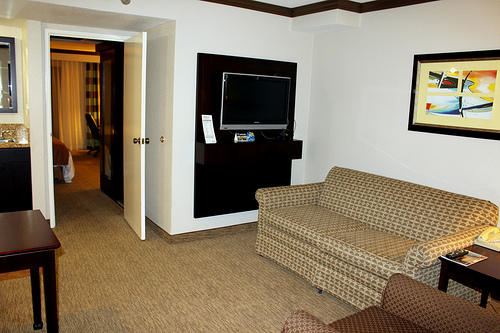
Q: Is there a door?
A: Yes, there is a door.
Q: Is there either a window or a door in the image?
A: Yes, there is a door.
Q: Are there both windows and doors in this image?
A: Yes, there are both a door and a window.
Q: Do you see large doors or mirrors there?
A: Yes, there is a large door.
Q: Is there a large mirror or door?
A: Yes, there is a large door.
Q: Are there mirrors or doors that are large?
A: Yes, the door is large.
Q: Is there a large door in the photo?
A: Yes, there is a large door.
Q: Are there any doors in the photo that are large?
A: Yes, there is a door that is large.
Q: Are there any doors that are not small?
A: Yes, there is a large door.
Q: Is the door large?
A: Yes, the door is large.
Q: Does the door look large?
A: Yes, the door is large.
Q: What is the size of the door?
A: The door is large.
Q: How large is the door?
A: The door is large.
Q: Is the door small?
A: No, the door is large.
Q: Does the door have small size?
A: No, the door is large.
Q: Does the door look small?
A: No, the door is large.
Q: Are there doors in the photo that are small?
A: No, there is a door but it is large.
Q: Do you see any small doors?
A: No, there is a door but it is large.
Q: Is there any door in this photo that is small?
A: No, there is a door but it is large.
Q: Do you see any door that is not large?
A: No, there is a door but it is large.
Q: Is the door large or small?
A: The door is large.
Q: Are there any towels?
A: No, there are no towels.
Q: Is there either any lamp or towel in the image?
A: No, there are no towels or lamps.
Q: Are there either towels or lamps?
A: No, there are no towels or lamps.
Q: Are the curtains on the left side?
A: Yes, the curtains are on the left of the image.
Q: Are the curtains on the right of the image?
A: No, the curtains are on the left of the image.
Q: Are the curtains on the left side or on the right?
A: The curtains are on the left of the image.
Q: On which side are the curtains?
A: The curtains are on the left of the image.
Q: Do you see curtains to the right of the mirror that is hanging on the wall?
A: Yes, there are curtains to the right of the mirror.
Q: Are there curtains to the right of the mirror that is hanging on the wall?
A: Yes, there are curtains to the right of the mirror.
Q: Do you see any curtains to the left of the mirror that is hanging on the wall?
A: No, the curtains are to the right of the mirror.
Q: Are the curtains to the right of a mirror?
A: Yes, the curtains are to the right of a mirror.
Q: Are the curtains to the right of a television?
A: No, the curtains are to the right of a mirror.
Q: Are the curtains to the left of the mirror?
A: No, the curtains are to the right of the mirror.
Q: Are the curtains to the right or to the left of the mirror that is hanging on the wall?
A: The curtains are to the right of the mirror.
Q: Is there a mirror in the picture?
A: Yes, there is a mirror.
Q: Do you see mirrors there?
A: Yes, there is a mirror.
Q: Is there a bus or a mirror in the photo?
A: Yes, there is a mirror.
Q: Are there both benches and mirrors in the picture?
A: No, there is a mirror but no benches.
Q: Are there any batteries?
A: No, there are no batteries.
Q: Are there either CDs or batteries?
A: No, there are no batteries or cds.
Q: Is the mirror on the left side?
A: Yes, the mirror is on the left of the image.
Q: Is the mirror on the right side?
A: No, the mirror is on the left of the image.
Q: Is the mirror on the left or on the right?
A: The mirror is on the left of the image.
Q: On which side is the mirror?
A: The mirror is on the left of the image.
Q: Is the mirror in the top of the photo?
A: Yes, the mirror is in the top of the image.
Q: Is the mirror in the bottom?
A: No, the mirror is in the top of the image.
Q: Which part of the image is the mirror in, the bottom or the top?
A: The mirror is in the top of the image.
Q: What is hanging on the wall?
A: The mirror is hanging on the wall.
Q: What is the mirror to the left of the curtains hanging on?
A: The mirror is hanging on the wall.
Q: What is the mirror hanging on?
A: The mirror is hanging on the wall.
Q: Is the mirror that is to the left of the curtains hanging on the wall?
A: Yes, the mirror is hanging on the wall.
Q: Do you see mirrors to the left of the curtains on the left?
A: Yes, there is a mirror to the left of the curtains.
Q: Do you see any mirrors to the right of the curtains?
A: No, the mirror is to the left of the curtains.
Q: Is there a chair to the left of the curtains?
A: No, there is a mirror to the left of the curtains.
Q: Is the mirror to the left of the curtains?
A: Yes, the mirror is to the left of the curtains.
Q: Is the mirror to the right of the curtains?
A: No, the mirror is to the left of the curtains.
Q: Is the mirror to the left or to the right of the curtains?
A: The mirror is to the left of the curtains.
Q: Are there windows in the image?
A: Yes, there is a window.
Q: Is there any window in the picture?
A: Yes, there is a window.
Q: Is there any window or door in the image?
A: Yes, there is a window.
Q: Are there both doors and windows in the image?
A: Yes, there are both a window and a door.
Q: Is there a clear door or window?
A: Yes, there is a clear window.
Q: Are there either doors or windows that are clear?
A: Yes, the window is clear.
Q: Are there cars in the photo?
A: No, there are no cars.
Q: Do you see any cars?
A: No, there are no cars.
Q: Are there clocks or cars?
A: No, there are no cars or clocks.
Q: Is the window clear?
A: Yes, the window is clear.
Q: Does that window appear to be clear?
A: Yes, the window is clear.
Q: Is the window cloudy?
A: No, the window is clear.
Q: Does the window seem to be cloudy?
A: No, the window is clear.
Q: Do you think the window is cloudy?
A: No, the window is clear.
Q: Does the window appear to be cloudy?
A: No, the window is clear.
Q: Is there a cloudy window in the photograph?
A: No, there is a window but it is clear.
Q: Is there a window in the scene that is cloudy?
A: No, there is a window but it is clear.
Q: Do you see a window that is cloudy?
A: No, there is a window but it is clear.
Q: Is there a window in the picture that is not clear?
A: No, there is a window but it is clear.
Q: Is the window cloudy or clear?
A: The window is clear.